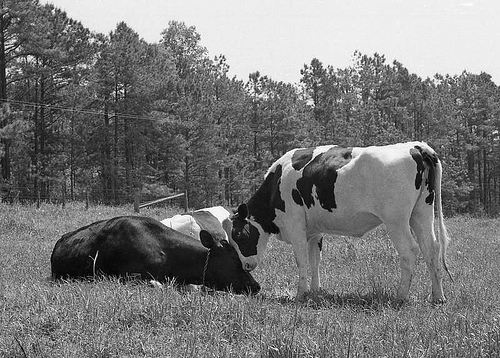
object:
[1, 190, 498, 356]
grass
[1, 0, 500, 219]
trees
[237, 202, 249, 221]
ear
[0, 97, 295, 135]
power lines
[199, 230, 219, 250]
ear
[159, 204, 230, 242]
cow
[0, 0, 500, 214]
trees field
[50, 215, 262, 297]
black cow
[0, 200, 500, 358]
ground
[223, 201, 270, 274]
head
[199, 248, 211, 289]
rope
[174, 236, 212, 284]
neck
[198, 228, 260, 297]
head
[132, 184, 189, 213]
gate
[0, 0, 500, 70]
sky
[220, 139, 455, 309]
cow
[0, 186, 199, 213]
posts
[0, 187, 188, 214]
fence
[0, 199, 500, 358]
field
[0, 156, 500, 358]
pasture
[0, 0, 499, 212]
background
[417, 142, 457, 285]
tail